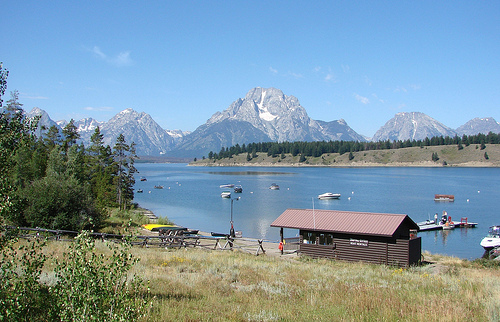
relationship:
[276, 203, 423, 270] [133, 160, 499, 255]
store on lake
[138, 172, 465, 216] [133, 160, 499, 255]
boats on water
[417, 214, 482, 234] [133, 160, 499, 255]
doc in water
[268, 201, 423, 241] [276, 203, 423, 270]
roof of store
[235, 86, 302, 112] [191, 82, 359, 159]
summit of mountain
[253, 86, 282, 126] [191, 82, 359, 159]
snow on mountain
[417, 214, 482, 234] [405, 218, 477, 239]
surface of pier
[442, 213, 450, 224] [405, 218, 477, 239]
person on pier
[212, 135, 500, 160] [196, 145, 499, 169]
forest in land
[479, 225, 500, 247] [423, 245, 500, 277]
boat near shore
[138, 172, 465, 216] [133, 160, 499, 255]
boats in water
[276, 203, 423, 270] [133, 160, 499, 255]
building by lake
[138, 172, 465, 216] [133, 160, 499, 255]
boats in lake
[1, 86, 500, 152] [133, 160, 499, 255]
mountains behind lake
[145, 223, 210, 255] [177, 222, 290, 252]
tables on shoreline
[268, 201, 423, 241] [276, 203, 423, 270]
roof on store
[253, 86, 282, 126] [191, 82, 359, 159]
snow on mountains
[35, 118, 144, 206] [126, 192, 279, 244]
trees along shoreline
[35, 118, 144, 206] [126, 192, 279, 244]
trees on shoreline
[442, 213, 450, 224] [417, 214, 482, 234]
people on doc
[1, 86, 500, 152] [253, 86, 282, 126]
mountains has snow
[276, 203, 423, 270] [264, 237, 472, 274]
store on shore